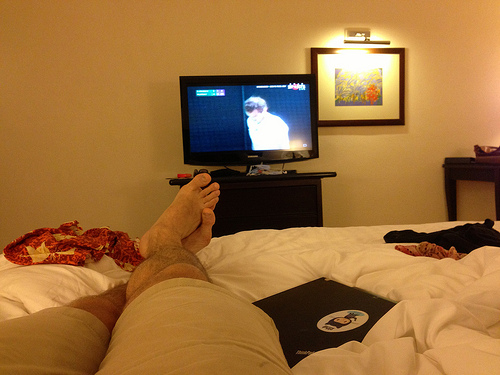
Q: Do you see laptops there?
A: Yes, there is a laptop.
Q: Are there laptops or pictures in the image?
A: Yes, there is a laptop.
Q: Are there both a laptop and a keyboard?
A: No, there is a laptop but no keyboards.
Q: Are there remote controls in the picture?
A: No, there are no remote controls.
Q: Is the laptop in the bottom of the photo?
A: Yes, the laptop is in the bottom of the image.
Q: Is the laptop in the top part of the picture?
A: No, the laptop is in the bottom of the image.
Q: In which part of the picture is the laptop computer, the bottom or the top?
A: The laptop computer is in the bottom of the image.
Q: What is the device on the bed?
A: The device is a laptop.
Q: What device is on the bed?
A: The device is a laptop.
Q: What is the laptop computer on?
A: The laptop computer is on the bed.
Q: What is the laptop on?
A: The laptop computer is on the bed.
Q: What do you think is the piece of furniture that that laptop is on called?
A: The piece of furniture is a bed.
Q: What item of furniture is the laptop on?
A: The laptop is on the bed.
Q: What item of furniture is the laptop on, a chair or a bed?
A: The laptop is on a bed.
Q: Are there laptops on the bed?
A: Yes, there is a laptop on the bed.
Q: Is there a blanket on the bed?
A: No, there is a laptop on the bed.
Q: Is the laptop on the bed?
A: Yes, the laptop is on the bed.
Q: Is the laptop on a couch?
A: No, the laptop is on the bed.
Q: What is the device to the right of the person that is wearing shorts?
A: The device is a laptop.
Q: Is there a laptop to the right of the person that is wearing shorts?
A: Yes, there is a laptop to the right of the person.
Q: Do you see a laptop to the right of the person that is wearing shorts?
A: Yes, there is a laptop to the right of the person.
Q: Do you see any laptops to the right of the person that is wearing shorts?
A: Yes, there is a laptop to the right of the person.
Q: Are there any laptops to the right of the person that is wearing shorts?
A: Yes, there is a laptop to the right of the person.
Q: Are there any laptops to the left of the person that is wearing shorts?
A: No, the laptop is to the right of the person.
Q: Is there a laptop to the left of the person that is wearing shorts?
A: No, the laptop is to the right of the person.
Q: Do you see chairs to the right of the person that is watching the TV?
A: No, there is a laptop to the right of the person.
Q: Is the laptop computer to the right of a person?
A: Yes, the laptop computer is to the right of a person.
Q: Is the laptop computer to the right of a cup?
A: No, the laptop computer is to the right of a person.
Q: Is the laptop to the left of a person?
A: No, the laptop is to the right of a person.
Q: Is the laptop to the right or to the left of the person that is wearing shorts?
A: The laptop is to the right of the person.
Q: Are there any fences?
A: No, there are no fences.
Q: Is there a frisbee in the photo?
A: No, there are no frisbees.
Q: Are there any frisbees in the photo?
A: No, there are no frisbees.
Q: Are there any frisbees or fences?
A: No, there are no frisbees or fences.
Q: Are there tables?
A: Yes, there is a table.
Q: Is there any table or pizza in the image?
A: Yes, there is a table.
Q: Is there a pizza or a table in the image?
A: Yes, there is a table.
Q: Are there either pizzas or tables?
A: Yes, there is a table.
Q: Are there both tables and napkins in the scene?
A: No, there is a table but no napkins.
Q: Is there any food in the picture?
A: No, there is no food.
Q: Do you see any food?
A: No, there is no food.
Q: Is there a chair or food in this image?
A: No, there are no food or chairs.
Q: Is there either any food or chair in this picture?
A: No, there are no food or chairs.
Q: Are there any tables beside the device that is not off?
A: Yes, there is a table beside the TV.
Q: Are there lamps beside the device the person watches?
A: No, there is a table beside the TV.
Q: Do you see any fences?
A: No, there are no fences.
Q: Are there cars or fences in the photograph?
A: No, there are no fences or cars.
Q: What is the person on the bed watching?
A: The person is watching the television.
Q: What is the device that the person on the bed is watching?
A: The device is a television.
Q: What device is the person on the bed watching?
A: The person is watching the television.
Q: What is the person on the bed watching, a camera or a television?
A: The person is watching a television.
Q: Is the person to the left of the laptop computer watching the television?
A: Yes, the person is watching the television.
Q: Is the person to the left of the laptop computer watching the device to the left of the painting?
A: Yes, the person is watching the television.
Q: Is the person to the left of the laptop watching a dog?
A: No, the person is watching the television.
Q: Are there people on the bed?
A: Yes, there is a person on the bed.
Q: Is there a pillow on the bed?
A: No, there is a person on the bed.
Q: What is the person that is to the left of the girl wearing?
A: The person is wearing shorts.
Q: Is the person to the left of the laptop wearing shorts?
A: Yes, the person is wearing shorts.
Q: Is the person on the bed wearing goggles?
A: No, the person is wearing shorts.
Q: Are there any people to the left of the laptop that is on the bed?
A: Yes, there is a person to the left of the laptop computer.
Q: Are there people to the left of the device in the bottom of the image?
A: Yes, there is a person to the left of the laptop computer.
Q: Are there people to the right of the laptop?
A: No, the person is to the left of the laptop.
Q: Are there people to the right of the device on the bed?
A: No, the person is to the left of the laptop.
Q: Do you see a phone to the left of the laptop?
A: No, there is a person to the left of the laptop.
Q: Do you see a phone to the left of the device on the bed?
A: No, there is a person to the left of the laptop.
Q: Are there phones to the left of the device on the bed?
A: No, there is a person to the left of the laptop.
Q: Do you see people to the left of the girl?
A: Yes, there is a person to the left of the girl.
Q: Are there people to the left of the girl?
A: Yes, there is a person to the left of the girl.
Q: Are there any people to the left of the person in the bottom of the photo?
A: Yes, there is a person to the left of the girl.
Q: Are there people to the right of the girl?
A: No, the person is to the left of the girl.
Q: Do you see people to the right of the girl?
A: No, the person is to the left of the girl.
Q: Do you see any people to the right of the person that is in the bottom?
A: No, the person is to the left of the girl.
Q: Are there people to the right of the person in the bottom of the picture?
A: No, the person is to the left of the girl.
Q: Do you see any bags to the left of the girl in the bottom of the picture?
A: No, there is a person to the left of the girl.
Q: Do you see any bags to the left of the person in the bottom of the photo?
A: No, there is a person to the left of the girl.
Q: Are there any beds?
A: Yes, there is a bed.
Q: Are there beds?
A: Yes, there is a bed.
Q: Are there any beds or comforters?
A: Yes, there is a bed.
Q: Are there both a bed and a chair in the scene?
A: No, there is a bed but no chairs.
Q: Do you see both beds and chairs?
A: No, there is a bed but no chairs.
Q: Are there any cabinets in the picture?
A: No, there are no cabinets.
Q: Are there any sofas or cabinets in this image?
A: No, there are no cabinets or sofas.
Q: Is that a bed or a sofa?
A: That is a bed.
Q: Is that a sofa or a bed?
A: That is a bed.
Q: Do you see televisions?
A: Yes, there is a television.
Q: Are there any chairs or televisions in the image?
A: Yes, there is a television.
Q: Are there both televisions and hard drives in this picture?
A: No, there is a television but no hard drives.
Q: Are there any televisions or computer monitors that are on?
A: Yes, the television is on.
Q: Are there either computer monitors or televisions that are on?
A: Yes, the television is on.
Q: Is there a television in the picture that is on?
A: Yes, there is a television that is on.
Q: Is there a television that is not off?
A: Yes, there is a television that is on.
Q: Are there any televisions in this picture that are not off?
A: Yes, there is a television that is on.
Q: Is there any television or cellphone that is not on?
A: No, there is a television but it is on.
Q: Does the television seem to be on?
A: Yes, the television is on.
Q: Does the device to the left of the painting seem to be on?
A: Yes, the TV is on.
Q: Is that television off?
A: No, the television is on.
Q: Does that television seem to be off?
A: No, the television is on.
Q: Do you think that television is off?
A: No, the television is on.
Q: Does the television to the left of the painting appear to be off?
A: No, the television is on.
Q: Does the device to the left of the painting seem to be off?
A: No, the television is on.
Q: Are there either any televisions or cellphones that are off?
A: No, there is a television but it is on.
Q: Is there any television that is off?
A: No, there is a television but it is on.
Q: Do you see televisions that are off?
A: No, there is a television but it is on.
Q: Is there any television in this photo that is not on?
A: No, there is a television but it is on.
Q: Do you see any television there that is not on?
A: No, there is a television but it is on.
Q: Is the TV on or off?
A: The TV is on.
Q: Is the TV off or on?
A: The TV is on.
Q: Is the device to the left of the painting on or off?
A: The TV is on.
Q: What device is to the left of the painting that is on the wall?
A: The device is a television.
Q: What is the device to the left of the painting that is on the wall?
A: The device is a television.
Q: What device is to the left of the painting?
A: The device is a television.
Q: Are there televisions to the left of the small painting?
A: Yes, there is a television to the left of the painting.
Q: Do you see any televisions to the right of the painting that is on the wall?
A: No, the television is to the left of the painting.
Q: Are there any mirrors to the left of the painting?
A: No, there is a television to the left of the painting.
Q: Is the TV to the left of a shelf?
A: No, the TV is to the left of a painting.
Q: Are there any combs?
A: No, there are no combs.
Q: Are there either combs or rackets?
A: No, there are no combs or rackets.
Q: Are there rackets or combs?
A: No, there are no combs or rackets.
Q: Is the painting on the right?
A: Yes, the painting is on the right of the image.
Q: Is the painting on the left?
A: No, the painting is on the right of the image.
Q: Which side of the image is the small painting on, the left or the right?
A: The painting is on the right of the image.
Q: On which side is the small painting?
A: The painting is on the right of the image.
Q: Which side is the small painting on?
A: The painting is on the right of the image.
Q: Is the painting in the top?
A: Yes, the painting is in the top of the image.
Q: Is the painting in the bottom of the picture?
A: No, the painting is in the top of the image.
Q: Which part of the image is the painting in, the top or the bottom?
A: The painting is in the top of the image.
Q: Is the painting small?
A: Yes, the painting is small.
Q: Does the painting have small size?
A: Yes, the painting is small.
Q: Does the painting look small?
A: Yes, the painting is small.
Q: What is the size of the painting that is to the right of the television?
A: The painting is small.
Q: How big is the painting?
A: The painting is small.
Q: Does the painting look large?
A: No, the painting is small.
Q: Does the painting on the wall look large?
A: No, the painting is small.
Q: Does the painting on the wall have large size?
A: No, the painting is small.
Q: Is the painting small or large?
A: The painting is small.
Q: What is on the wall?
A: The painting is on the wall.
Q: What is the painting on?
A: The painting is on the wall.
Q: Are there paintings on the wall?
A: Yes, there is a painting on the wall.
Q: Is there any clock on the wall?
A: No, there is a painting on the wall.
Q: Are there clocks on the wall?
A: No, there is a painting on the wall.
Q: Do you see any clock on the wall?
A: No, there is a painting on the wall.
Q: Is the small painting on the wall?
A: Yes, the painting is on the wall.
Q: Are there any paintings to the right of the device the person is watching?
A: Yes, there is a painting to the right of the television.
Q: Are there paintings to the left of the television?
A: No, the painting is to the right of the television.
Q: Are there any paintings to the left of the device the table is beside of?
A: No, the painting is to the right of the television.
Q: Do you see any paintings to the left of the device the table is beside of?
A: No, the painting is to the right of the television.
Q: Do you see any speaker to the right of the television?
A: No, there is a painting to the right of the television.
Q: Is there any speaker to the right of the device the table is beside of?
A: No, there is a painting to the right of the television.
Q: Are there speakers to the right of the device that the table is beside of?
A: No, there is a painting to the right of the television.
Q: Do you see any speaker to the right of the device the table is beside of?
A: No, there is a painting to the right of the television.